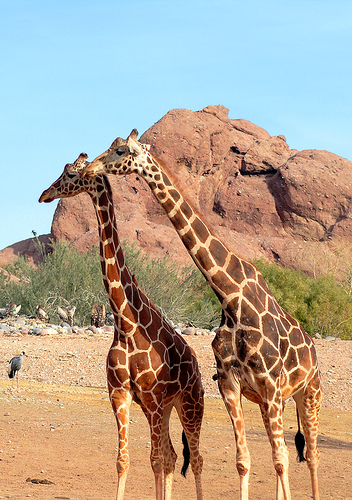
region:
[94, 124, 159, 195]
the giraffe has ears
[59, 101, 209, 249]
the giraffe has ears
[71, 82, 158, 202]
the giraffe has ears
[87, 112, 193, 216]
the giraffe has ears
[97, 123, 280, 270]
the giraffe has ears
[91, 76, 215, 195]
the giraffe has ears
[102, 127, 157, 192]
giraffe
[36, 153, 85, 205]
giraffe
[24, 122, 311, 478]
spotted giraffes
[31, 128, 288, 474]
tan and brown spotted giraffes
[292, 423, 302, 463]
long black tail of adult giraffe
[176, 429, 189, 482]
long black tail of giraffe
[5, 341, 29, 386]
bird standing on rocky soil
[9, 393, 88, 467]
tan and brown dry soil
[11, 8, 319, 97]
white clouds against blue sky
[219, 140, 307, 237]
large tan rocks and boulders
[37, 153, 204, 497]
a tall tan and brown spotted giraffe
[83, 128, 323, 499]
a tall tan and brown spotted giraffe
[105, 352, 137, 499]
the long tan and brown leg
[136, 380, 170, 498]
the long tan and brown leg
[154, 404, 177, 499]
the long tan and brown leg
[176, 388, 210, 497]
the long tan and brown leg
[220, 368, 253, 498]
the long tan and brown leg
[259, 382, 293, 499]
the long tan and brown leg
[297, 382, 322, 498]
the long tan and brown leg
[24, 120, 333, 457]
two giraffes side by side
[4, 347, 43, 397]
bird standing on dirt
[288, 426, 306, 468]
black hair on tail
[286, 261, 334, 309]
bushes with green leaves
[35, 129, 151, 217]
two heads looking left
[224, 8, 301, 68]
clear blue daytime sky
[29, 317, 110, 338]
line of rocks on hill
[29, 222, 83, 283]
brush in front of rock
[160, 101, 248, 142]
top of red rock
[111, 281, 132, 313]
brown spot on giraffe neck